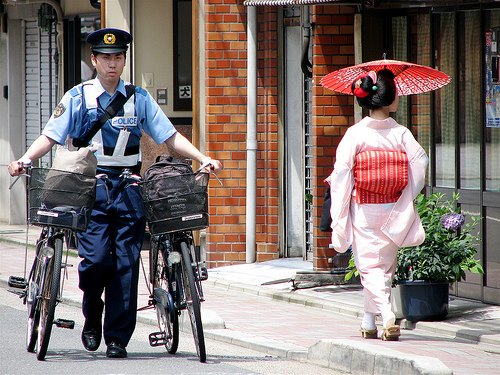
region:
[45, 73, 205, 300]
a policeman in uniform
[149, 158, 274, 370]
a policeman in uniform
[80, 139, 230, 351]
a policeman in uniform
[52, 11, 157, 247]
a policeman in uniform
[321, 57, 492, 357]
the lady is carrying a parasol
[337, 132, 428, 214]
the lady has a red back pack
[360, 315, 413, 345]
the lady is wearing clogs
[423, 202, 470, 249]
a purple flower is on the bush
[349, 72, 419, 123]
the lady has real dark hair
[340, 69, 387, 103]
she has colorful ornaments in her hair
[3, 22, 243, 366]
the policeman has two bikes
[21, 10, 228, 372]
his uniform is blue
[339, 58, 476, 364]
the lady is looking in the window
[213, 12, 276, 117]
the building is made of brick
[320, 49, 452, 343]
a traditional geisha of Japan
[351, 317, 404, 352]
geta shoes resemble clogs and flipflops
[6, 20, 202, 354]
a policeman walks two bicycles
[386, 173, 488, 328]
a potted plant with a purple flower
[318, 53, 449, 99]
a red print paper parasol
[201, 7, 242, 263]
a varigated brick wall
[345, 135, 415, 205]
a red striped obi tied in a drum bow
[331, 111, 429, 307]
pale pink geisha kimono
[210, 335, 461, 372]
a stone curb at the road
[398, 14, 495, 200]
curtained windows with dark brown frames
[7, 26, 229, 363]
A police man walking with two bicycles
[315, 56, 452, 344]
A short woman wearing pink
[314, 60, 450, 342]
An Asian woman holding a red parasol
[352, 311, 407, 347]
A pair of wooden sandals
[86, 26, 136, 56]
A black police hat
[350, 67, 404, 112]
A woman with her hair up in an intricate bun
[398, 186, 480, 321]
A potted plant with a purple flower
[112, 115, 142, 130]
A police tag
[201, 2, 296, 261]
A light red brick wall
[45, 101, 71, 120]
A police badge on a sleeve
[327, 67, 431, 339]
Woman holding red umbrella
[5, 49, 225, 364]
Man pushing two bikes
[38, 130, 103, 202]
Tan bag in black basket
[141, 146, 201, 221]
Black bag in basket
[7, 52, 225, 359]
Man is a police officer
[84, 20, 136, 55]
Hat on man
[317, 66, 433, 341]
Woman wearing pink kimono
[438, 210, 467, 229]
Flower is purple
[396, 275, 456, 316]
Pot is big and black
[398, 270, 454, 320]
Pot on ground